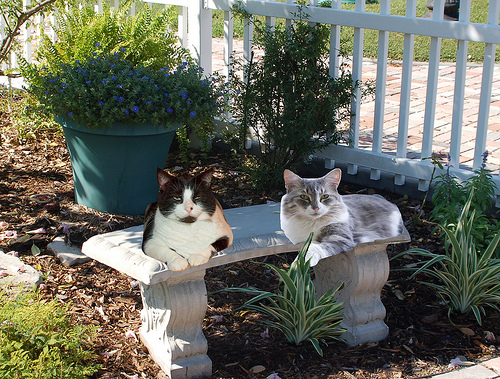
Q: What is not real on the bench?
A: Cat's have been photoshopped into the picture.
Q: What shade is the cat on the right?
A: Cat is grey and white.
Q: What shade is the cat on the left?
A: Cat is yellow black and white.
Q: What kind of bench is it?
A: This is a stone bench.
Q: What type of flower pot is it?
A: The flower pot is plastic and green.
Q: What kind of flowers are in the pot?
A: Small and blue.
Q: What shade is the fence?
A: The fence is white.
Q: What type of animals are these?
A: Cats.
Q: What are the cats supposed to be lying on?
A: Bench.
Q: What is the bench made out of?
A: Concrete.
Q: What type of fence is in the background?
A: White picket fence.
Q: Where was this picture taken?
A: Flower, and Plant Garden.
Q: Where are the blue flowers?
A: Flower Pot.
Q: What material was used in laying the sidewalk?
A: Brick.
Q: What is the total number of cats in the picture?
A: 2.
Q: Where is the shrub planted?
A: Next to fence.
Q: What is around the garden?
A: A white fence.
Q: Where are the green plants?
A: In the garden.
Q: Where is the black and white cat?
A: On the bench.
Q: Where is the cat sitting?
A: On the bench.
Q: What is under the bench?
A: A plant.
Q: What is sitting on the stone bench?
A: Two cats.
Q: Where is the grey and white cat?
A: On the bench.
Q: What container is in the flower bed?
A: A green pot.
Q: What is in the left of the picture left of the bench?
A: A small green shrub.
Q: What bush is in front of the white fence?
A: A dark green plant.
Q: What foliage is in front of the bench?
A: Light green plants.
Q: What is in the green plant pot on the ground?
A: A blue flowering plant.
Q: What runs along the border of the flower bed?
A: A white picket fence.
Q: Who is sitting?
A: Cats.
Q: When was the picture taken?
A: Daytime.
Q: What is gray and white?
A: Cat on right.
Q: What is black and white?
A: Cat on left.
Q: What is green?
A: Plants.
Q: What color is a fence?
A: White.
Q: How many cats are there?
A: Two.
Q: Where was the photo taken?
A: The garden.